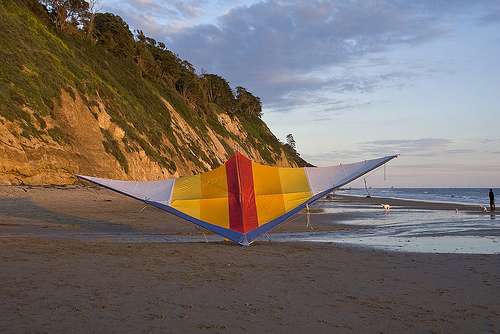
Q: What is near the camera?
A: Kite.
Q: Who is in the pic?
A: No one.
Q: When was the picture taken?
A: During the day.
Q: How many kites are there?
A: 1.